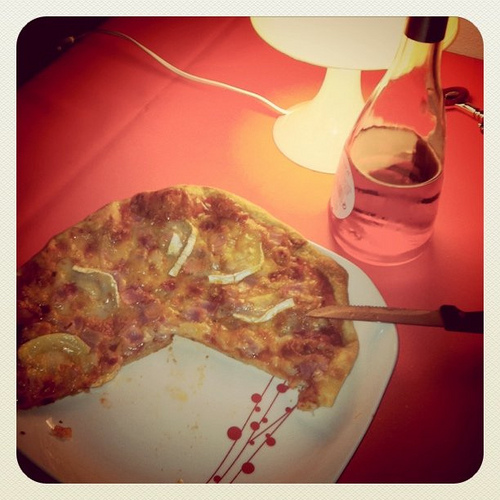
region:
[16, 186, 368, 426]
a partially eaten pizza.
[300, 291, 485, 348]
a knife on a plate.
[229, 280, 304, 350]
toppings on a pizza.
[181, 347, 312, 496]
flower design on a white tray.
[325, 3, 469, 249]
a bottle of carbonated water.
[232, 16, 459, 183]
a lamp sitting on a table.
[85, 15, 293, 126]
a chord for a lamp.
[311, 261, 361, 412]
a pizza crust.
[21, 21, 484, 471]
a red table with pizza on it.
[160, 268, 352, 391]
a slice of cheesy pizza.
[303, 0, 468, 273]
a bottle of wine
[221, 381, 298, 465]
a few red dots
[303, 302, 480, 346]
a black handled knife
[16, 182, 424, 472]
a square plate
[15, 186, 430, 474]
a white and red plate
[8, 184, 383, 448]
a half eaten pizza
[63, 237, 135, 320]
a melted piece of brie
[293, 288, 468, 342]
a serrated steak knife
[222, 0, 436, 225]
a glowing white table lamp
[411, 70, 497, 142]
a metal wine key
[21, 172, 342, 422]
pizza on a plate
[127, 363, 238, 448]
white plater unde pizza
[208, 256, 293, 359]
cheese on the pizza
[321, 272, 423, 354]
knife on the plate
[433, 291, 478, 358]
black handle of the knife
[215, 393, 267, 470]
red circles on plate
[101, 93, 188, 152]
red table under plate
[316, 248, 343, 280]
brown crust of pizza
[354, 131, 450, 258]
liquid in a glass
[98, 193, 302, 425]
pizza with pices taken out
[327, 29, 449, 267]
A bottle of clear liquid.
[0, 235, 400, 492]
White plate with red decoration on it.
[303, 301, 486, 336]
Silver blade on a knife and a black handle.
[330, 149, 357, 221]
White label on a bottle.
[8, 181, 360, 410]
Pizza on a plate.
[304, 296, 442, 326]
Silver blade of a knife.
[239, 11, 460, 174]
A lamp illuminated on the table.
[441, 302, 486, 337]
Black handle of a knife.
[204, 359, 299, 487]
Red decoration on a white plate.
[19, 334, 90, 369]
Mushroom on a pizza to the left.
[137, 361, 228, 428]
white plate under pizza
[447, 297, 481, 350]
black handle of knife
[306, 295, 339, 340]
tip of knife on pizza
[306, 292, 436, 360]
silver part of knife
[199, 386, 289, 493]
red circles on plate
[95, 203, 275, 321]
cheese on the pizza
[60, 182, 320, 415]
pizza with pieces missing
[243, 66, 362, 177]
light on table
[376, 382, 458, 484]
red table under pizza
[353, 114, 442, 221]
glass with liquid in it